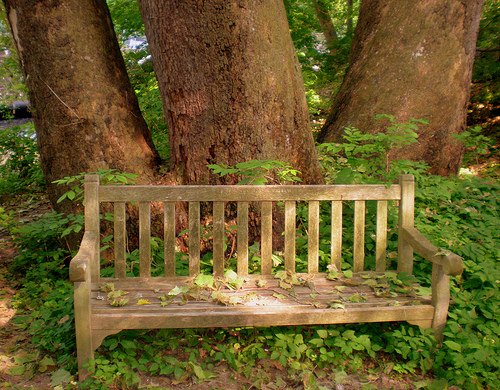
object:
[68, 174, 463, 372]
bench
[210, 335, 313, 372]
plant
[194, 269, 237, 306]
leaves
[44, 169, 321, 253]
stump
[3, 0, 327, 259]
tree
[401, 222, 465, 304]
arm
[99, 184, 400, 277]
back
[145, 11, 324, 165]
trunk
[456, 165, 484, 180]
sun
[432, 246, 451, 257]
leaf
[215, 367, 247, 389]
dirt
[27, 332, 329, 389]
ground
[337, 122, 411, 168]
plant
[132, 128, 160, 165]
bark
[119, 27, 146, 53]
sky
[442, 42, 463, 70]
moss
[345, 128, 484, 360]
bushes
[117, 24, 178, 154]
bushes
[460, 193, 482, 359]
ivy